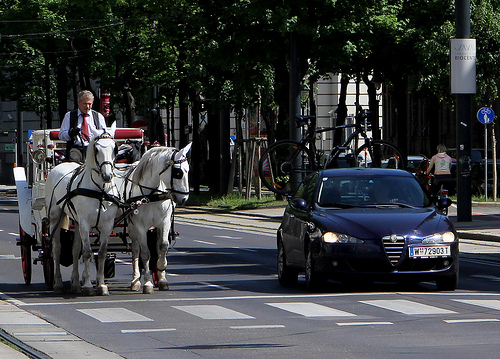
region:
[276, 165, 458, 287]
a black car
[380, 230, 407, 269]
small upside down triangle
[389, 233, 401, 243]
car logo symbol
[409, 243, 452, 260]
license plate on front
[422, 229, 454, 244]
headlight on car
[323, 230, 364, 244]
headlight on car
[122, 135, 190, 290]
white horse left looking to car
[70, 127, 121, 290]
white horse on right faced forward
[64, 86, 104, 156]
man driving horse carriage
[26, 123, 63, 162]
horses are pulling carriage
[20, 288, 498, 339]
white lines painted on ground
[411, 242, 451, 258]
white license plate on car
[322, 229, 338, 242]
the car's right headlight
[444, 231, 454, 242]
the car's left headlight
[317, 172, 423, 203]
the windshield on the car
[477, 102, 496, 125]
blue sign on pole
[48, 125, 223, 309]
2 white horses in street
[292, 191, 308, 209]
right side view mirror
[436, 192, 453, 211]
left side view mirror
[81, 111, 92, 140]
tie on the man's shirt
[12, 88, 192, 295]
A horse drawn carriage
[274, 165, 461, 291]
A black car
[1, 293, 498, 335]
A cross walk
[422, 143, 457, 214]
A person riding a bike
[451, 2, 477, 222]
A post with a sign on it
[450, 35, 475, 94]
A white sign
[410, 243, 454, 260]
A car's licence plate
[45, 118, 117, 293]
A white horse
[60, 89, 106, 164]
A man who is driving a carriage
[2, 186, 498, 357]
A tree lines road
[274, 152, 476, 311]
The black car in the street.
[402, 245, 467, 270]
The license plate on the car.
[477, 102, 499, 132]
Circle shaped blue sign.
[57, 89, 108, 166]
The man sitting on the horse.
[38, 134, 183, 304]
The two horses in the street.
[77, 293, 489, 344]
Lines painted on the street.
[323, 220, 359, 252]
The cars right front light.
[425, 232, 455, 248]
The cars left front light.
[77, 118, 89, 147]
The mans red tie.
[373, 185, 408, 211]
Person driving a car.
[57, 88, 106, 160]
Man wearing a red tie and black vest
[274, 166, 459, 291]
Dark blue car with illuminated headlights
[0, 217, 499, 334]
White stripes on a black road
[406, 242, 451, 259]
Very long license plate with black numbers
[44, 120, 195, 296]
Two white horses with blinders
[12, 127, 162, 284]
White carriage with red accents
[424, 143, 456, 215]
Woman in a hoodie riding a bicycle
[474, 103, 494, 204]
Blue cirucular road sign on a pole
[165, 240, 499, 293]
Shadows of trees on the road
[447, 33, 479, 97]
White sign wrapped around a pole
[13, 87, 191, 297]
man riding a horse carriage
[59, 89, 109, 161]
man wearing a red tie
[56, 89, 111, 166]
man wearing black vest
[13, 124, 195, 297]
two horses pulling carriage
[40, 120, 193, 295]
both horses are white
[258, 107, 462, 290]
bicycle in back of car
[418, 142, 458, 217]
person riding a bike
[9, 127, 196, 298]
two white horses pulling a carriage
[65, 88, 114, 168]
a man sitting on a carriage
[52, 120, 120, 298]
a white horse on a street